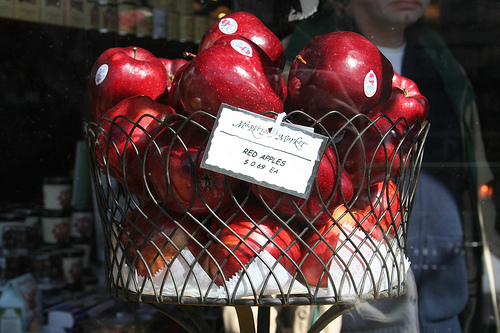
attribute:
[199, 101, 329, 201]
tag — white, black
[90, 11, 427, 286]
apples — red, sold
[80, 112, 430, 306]
basket — wire, black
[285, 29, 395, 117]
apple — red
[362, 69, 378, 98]
sticker — white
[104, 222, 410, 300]
lining — paper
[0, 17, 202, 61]
shelf — high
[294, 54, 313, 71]
stem — brown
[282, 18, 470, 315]
jacket — black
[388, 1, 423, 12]
mouth — frowning